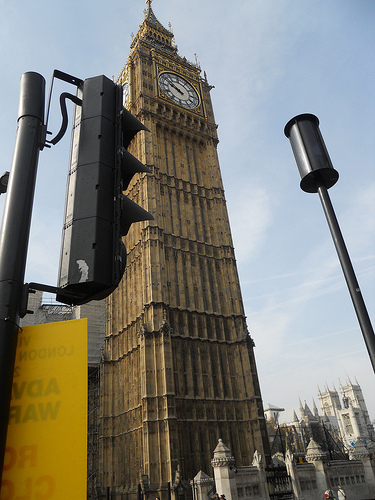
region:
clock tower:
[132, 20, 271, 453]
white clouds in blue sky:
[248, 27, 302, 69]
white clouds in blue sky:
[271, 209, 310, 278]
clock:
[147, 68, 195, 125]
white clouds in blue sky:
[263, 307, 339, 355]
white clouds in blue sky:
[263, 276, 349, 344]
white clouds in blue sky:
[233, 66, 280, 101]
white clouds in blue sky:
[26, 15, 93, 60]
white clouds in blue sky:
[231, 44, 272, 69]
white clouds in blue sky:
[250, 41, 303, 82]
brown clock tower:
[141, 14, 253, 484]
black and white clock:
[157, 67, 193, 131]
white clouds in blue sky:
[22, 25, 50, 65]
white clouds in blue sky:
[33, 1, 90, 46]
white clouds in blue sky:
[52, 23, 75, 47]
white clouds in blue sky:
[184, 25, 211, 42]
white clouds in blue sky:
[216, 5, 254, 46]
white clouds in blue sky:
[246, 6, 302, 58]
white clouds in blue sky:
[229, 14, 268, 72]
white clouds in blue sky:
[301, 15, 352, 41]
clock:
[158, 65, 210, 114]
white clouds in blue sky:
[237, 249, 275, 294]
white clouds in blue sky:
[260, 292, 291, 322]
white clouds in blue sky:
[246, 207, 307, 265]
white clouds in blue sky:
[223, 97, 279, 151]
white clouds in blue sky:
[317, 73, 370, 113]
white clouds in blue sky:
[264, 31, 327, 73]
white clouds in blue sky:
[42, 14, 67, 46]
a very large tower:
[97, 1, 282, 497]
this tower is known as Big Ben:
[88, 0, 307, 498]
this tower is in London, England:
[83, 3, 283, 495]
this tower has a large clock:
[83, 3, 291, 497]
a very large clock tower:
[68, 0, 274, 491]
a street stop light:
[35, 38, 157, 314]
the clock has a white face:
[136, 59, 228, 114]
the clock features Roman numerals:
[148, 65, 206, 117]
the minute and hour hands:
[153, 61, 190, 95]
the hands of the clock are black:
[148, 62, 202, 105]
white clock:
[146, 63, 216, 131]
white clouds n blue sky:
[219, 7, 282, 62]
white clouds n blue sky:
[290, 2, 333, 67]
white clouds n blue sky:
[231, 87, 296, 123]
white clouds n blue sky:
[236, 171, 273, 221]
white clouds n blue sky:
[270, 222, 303, 270]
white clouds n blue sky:
[266, 290, 333, 337]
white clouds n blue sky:
[46, 21, 92, 46]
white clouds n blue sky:
[234, 36, 327, 97]